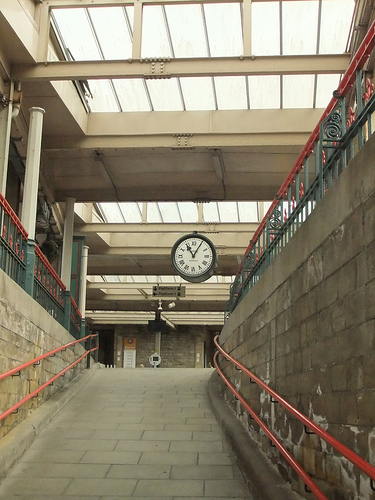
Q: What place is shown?
A: It is a station.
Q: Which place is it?
A: It is a station.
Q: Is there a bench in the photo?
A: No, there are no benches.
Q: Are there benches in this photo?
A: No, there are no benches.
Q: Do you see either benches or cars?
A: No, there are no benches or cars.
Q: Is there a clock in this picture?
A: Yes, there is a clock.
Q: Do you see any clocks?
A: Yes, there is a clock.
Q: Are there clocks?
A: Yes, there is a clock.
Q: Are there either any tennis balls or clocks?
A: Yes, there is a clock.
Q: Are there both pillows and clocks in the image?
A: No, there is a clock but no pillows.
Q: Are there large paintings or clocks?
A: Yes, there is a large clock.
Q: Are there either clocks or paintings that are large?
A: Yes, the clock is large.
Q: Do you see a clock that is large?
A: Yes, there is a large clock.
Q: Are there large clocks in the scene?
A: Yes, there is a large clock.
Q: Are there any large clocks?
A: Yes, there is a large clock.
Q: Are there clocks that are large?
A: Yes, there is a large clock.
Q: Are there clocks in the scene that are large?
A: Yes, there is a clock that is large.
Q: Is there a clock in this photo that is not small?
A: Yes, there is a large clock.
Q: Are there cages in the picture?
A: No, there are no cages.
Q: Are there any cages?
A: No, there are no cages.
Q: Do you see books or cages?
A: No, there are no cages or books.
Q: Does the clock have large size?
A: Yes, the clock is large.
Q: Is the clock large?
A: Yes, the clock is large.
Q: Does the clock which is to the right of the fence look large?
A: Yes, the clock is large.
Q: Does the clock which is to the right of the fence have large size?
A: Yes, the clock is large.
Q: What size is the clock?
A: The clock is large.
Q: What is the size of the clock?
A: The clock is large.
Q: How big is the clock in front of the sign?
A: The clock is large.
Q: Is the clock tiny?
A: No, the clock is large.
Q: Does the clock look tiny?
A: No, the clock is large.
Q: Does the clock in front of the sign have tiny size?
A: No, the clock is large.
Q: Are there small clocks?
A: No, there is a clock but it is large.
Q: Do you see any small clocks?
A: No, there is a clock but it is large.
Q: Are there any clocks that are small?
A: No, there is a clock but it is large.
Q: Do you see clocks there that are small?
A: No, there is a clock but it is large.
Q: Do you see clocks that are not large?
A: No, there is a clock but it is large.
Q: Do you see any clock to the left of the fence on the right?
A: Yes, there is a clock to the left of the fence.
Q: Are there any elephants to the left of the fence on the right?
A: No, there is a clock to the left of the fence.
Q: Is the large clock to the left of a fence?
A: Yes, the clock is to the left of a fence.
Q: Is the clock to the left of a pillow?
A: No, the clock is to the left of a fence.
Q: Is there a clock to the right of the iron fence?
A: Yes, there is a clock to the right of the fence.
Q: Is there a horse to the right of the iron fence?
A: No, there is a clock to the right of the fence.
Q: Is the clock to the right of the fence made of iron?
A: Yes, the clock is to the right of the fence.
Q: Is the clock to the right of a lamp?
A: No, the clock is to the right of the fence.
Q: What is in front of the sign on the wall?
A: The clock is in front of the sign.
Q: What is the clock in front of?
A: The clock is in front of the sign.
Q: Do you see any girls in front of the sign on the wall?
A: No, there is a clock in front of the sign.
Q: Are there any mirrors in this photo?
A: No, there are no mirrors.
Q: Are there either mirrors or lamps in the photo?
A: No, there are no mirrors or lamps.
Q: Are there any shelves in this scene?
A: No, there are no shelves.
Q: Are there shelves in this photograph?
A: No, there are no shelves.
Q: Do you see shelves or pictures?
A: No, there are no shelves or pictures.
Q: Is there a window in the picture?
A: Yes, there are windows.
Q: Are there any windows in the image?
A: Yes, there are windows.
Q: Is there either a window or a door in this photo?
A: Yes, there are windows.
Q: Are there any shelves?
A: No, there are no shelves.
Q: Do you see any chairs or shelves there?
A: No, there are no shelves or chairs.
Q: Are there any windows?
A: Yes, there are windows.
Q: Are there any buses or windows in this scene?
A: Yes, there are windows.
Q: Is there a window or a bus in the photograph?
A: Yes, there are windows.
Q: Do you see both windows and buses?
A: No, there are windows but no buses.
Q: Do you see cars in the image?
A: No, there are no cars.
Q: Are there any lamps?
A: No, there are no lamps.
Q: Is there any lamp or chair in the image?
A: No, there are no lamps or chairs.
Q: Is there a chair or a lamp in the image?
A: No, there are no lamps or chairs.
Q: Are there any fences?
A: Yes, there is a fence.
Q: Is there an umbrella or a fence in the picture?
A: Yes, there is a fence.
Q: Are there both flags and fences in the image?
A: No, there is a fence but no flags.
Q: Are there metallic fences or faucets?
A: Yes, there is a metal fence.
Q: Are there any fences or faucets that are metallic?
A: Yes, the fence is metallic.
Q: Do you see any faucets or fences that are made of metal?
A: Yes, the fence is made of metal.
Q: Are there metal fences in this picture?
A: Yes, there is a metal fence.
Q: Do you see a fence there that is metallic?
A: Yes, there is a fence that is metallic.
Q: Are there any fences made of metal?
A: Yes, there is a fence that is made of metal.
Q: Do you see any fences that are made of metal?
A: Yes, there is a fence that is made of metal.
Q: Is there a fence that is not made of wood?
A: Yes, there is a fence that is made of metal.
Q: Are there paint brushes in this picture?
A: No, there are no paint brushes.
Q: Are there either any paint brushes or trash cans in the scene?
A: No, there are no paint brushes or trash cans.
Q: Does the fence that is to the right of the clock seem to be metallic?
A: Yes, the fence is metallic.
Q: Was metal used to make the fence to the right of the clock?
A: Yes, the fence is made of metal.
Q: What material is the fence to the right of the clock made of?
A: The fence is made of metal.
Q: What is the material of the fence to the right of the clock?
A: The fence is made of metal.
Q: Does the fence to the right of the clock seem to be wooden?
A: No, the fence is metallic.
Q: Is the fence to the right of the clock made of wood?
A: No, the fence is made of metal.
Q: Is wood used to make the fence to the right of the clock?
A: No, the fence is made of metal.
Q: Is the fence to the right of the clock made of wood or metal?
A: The fence is made of metal.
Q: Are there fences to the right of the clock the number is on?
A: Yes, there is a fence to the right of the clock.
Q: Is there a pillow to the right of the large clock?
A: No, there is a fence to the right of the clock.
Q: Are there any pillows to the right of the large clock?
A: No, there is a fence to the right of the clock.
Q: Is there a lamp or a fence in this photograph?
A: Yes, there is a fence.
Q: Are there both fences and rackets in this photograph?
A: No, there is a fence but no rackets.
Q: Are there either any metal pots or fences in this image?
A: Yes, there is a metal fence.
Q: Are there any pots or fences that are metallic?
A: Yes, the fence is metallic.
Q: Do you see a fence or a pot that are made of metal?
A: Yes, the fence is made of metal.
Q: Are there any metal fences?
A: Yes, there is a metal fence.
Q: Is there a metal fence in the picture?
A: Yes, there is a metal fence.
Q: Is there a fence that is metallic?
A: Yes, there is a fence that is metallic.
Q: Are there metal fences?
A: Yes, there is a fence that is made of metal.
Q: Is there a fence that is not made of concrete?
A: Yes, there is a fence that is made of metal.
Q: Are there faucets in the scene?
A: No, there are no faucets.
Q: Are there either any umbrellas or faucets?
A: No, there are no faucets or umbrellas.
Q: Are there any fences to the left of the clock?
A: Yes, there is a fence to the left of the clock.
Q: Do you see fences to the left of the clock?
A: Yes, there is a fence to the left of the clock.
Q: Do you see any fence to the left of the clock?
A: Yes, there is a fence to the left of the clock.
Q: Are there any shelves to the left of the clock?
A: No, there is a fence to the left of the clock.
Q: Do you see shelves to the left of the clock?
A: No, there is a fence to the left of the clock.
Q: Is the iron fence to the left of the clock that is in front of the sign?
A: Yes, the fence is to the left of the clock.